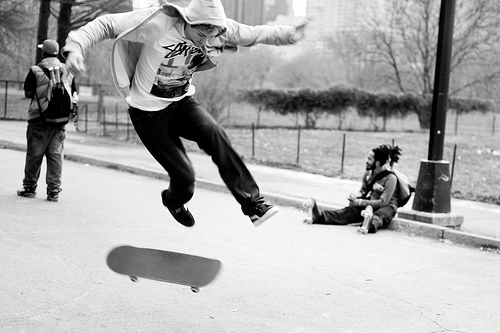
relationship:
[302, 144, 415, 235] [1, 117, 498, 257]
man sitting on sidewalk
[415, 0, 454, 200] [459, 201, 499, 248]
pole on top of sidewalk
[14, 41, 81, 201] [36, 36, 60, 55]
man wearing baseball cap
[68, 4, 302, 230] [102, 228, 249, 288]
man riding on skateboard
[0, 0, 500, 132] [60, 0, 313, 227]
tree behind man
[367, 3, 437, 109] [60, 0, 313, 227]
tree behind man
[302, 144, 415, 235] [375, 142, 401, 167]
man has ponytail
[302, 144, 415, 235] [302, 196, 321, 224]
man wearing skate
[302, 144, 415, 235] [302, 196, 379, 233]
man wearing rollerskates.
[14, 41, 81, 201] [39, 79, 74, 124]
man has backpack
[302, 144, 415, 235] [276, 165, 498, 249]
man sitting on sidewalk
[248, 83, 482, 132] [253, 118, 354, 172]
vines on fence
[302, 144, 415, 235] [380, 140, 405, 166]
man has pony tail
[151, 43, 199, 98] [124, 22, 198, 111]
print on shirt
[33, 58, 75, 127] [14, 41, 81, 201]
backpack on man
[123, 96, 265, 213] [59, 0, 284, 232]
pants on skater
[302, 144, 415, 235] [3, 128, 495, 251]
man sitting on curb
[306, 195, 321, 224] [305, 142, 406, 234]
skate on man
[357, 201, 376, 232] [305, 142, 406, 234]
skate on man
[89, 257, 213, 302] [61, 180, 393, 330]
grey concrete of road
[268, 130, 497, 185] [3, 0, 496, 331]
grass of park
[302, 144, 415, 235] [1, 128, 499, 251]
man sitting at sidewalk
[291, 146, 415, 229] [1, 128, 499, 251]
man sitting at sidewalk